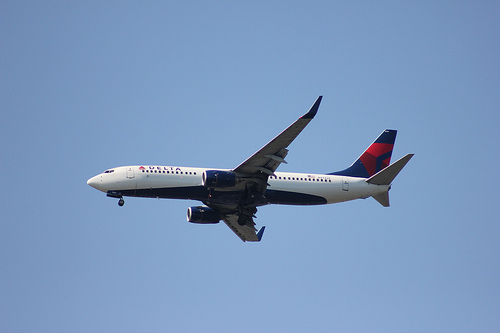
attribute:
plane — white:
[80, 90, 423, 246]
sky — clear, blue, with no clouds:
[3, 0, 498, 325]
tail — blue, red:
[335, 120, 428, 212]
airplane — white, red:
[77, 94, 421, 244]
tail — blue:
[337, 120, 416, 210]